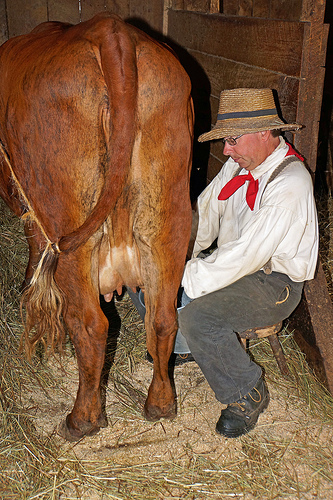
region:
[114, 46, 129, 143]
The tail of the cow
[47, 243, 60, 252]
Tail tied with a string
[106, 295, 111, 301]
The teat of the cow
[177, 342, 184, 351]
The outside surface of a bucket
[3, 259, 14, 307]
Straw on the ground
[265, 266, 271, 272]
Suspenders holding trousers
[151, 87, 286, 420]
man milking a cow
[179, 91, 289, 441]
man wearing a straw hat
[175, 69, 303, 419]
man wearing red handkerchief around his neck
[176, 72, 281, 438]
man wearing brown boots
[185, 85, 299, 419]
man wearing eyeglasses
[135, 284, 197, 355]
silver pail for milk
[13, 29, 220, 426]
large brown cow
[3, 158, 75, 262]
rope on cow's tail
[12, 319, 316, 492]
hay covering the ground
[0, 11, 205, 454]
a large brown cow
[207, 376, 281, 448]
black shoes on feet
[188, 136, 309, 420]
a white shirt and gray pants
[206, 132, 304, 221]
a red scarf around neck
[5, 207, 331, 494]
straw covers the ground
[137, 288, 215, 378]
a bucket between his knees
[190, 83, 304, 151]
a hat on his head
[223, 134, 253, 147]
glasses on his face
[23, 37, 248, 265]
back of the animal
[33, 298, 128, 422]
leg of the animal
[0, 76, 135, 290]
tail of the animal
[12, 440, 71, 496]
hay on the ground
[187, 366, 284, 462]
shoe of the man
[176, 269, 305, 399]
black pants on the man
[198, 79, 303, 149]
hat on man's head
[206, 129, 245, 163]
glasses on man's face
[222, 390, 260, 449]
Man wearing black boots.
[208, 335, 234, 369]
Man wearing gray pants.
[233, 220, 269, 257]
Man wearing white shirt.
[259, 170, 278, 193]
Man wearing brown suspenders.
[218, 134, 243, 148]
Glasses on man's face.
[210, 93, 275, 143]
Hat on man's head.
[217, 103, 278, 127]
Black band around man's hat.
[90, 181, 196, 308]
Man milking brown cow.